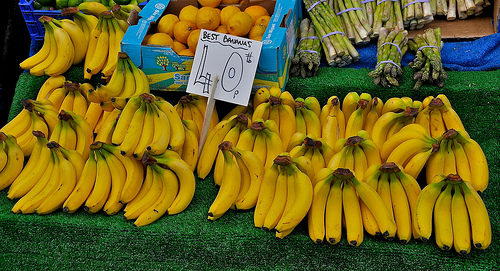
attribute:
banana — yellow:
[204, 136, 241, 215]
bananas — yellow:
[221, 82, 493, 254]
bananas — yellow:
[216, 101, 483, 249]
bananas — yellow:
[2, 77, 180, 218]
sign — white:
[166, 17, 246, 107]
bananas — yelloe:
[272, 127, 498, 235]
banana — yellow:
[134, 160, 178, 226]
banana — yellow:
[152, 154, 194, 216]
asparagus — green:
[407, 26, 450, 89]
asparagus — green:
[370, 20, 413, 85]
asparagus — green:
[292, 2, 365, 73]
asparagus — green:
[284, 0, 484, 85]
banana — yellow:
[154, 172, 176, 222]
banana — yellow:
[141, 176, 159, 208]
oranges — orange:
[175, 4, 207, 29]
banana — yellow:
[254, 160, 274, 227]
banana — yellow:
[264, 167, 284, 227]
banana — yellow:
[277, 164, 312, 231]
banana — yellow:
[310, 170, 325, 242]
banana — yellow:
[325, 174, 340, 244]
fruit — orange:
[195, 6, 219, 28]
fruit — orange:
[147, 32, 174, 49]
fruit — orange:
[245, 5, 268, 25]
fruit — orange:
[227, 11, 253, 35]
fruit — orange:
[187, 27, 202, 52]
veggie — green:
[377, 27, 387, 74]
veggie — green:
[423, 27, 440, 79]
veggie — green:
[300, 17, 309, 64]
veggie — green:
[397, 43, 407, 75]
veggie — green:
[302, 0, 337, 57]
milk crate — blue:
[13, 0, 81, 55]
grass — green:
[4, 204, 498, 270]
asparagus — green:
[351, 8, 399, 78]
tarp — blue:
[321, 31, 498, 71]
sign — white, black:
[182, 26, 269, 111]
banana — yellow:
[310, 168, 375, 248]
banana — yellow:
[253, 150, 325, 230]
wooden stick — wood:
[187, 84, 220, 160]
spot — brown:
[152, 207, 159, 212]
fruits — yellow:
[43, 11, 271, 214]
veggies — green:
[300, 4, 467, 89]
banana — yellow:
[281, 169, 311, 231]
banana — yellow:
[310, 173, 332, 239]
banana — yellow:
[46, 25, 71, 77]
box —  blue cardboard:
[119, 0, 309, 95]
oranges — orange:
[210, 17, 243, 34]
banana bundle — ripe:
[204, 141, 266, 218]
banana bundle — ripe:
[253, 150, 313, 238]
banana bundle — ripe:
[308, 166, 395, 247]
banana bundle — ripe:
[412, 172, 491, 254]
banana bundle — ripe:
[63, 140, 145, 215]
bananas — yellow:
[31, 75, 477, 250]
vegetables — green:
[365, 28, 446, 85]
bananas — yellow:
[2, 50, 192, 231]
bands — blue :
[325, 29, 344, 35]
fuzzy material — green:
[23, 226, 128, 269]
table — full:
[6, 10, 498, 247]